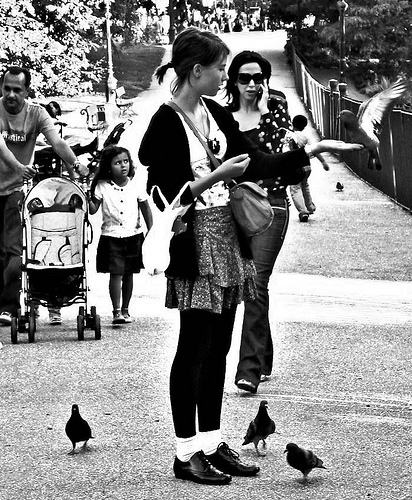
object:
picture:
[0, 0, 412, 500]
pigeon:
[335, 77, 408, 171]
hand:
[314, 137, 365, 154]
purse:
[162, 100, 275, 239]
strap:
[163, 100, 233, 187]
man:
[0, 65, 90, 327]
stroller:
[8, 161, 102, 345]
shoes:
[173, 449, 232, 486]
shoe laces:
[216, 441, 241, 464]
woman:
[221, 49, 293, 394]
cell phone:
[256, 76, 269, 100]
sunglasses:
[234, 71, 267, 86]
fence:
[290, 44, 412, 215]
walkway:
[124, 23, 412, 282]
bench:
[80, 103, 110, 140]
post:
[101, 0, 121, 120]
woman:
[137, 25, 367, 484]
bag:
[141, 181, 198, 277]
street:
[0, 315, 412, 500]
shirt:
[93, 176, 149, 240]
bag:
[229, 180, 275, 238]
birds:
[64, 403, 96, 456]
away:
[113, 159, 129, 166]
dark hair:
[90, 146, 135, 201]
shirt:
[136, 94, 311, 279]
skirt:
[95, 231, 145, 275]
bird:
[283, 442, 328, 486]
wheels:
[92, 313, 103, 342]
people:
[290, 113, 330, 223]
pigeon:
[240, 395, 280, 459]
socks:
[175, 435, 201, 464]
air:
[281, 16, 411, 171]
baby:
[28, 204, 82, 266]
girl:
[89, 146, 154, 324]